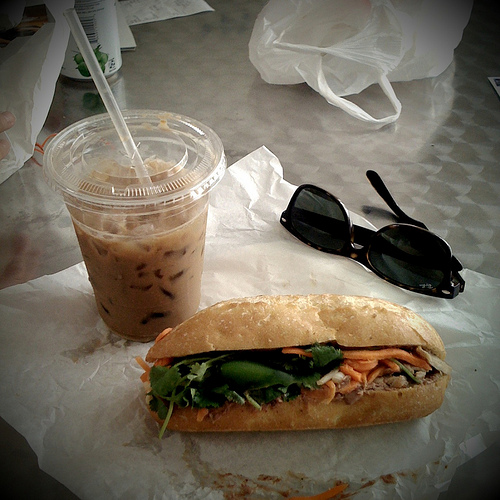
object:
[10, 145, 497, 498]
wrapper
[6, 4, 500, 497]
counter top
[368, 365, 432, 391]
shredded cheese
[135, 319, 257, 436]
end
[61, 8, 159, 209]
straw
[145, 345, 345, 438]
lettuce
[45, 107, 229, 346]
cup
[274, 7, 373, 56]
handle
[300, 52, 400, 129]
handle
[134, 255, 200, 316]
ice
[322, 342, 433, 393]
carrots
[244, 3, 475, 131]
bag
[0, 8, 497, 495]
top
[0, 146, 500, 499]
paper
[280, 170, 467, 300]
sunglasses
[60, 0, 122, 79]
aluminum can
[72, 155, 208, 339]
coffee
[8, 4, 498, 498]
table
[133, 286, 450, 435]
bun